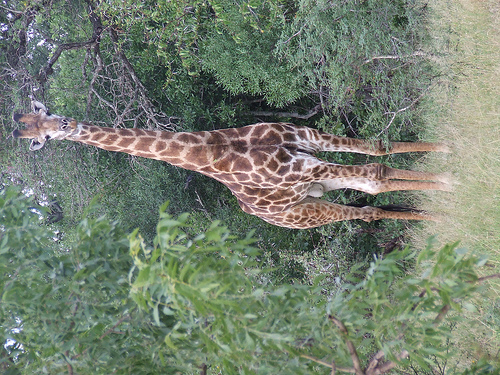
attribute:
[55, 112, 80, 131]
nose — black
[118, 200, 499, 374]
shrub — covered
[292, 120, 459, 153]
leg — long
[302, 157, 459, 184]
leg — long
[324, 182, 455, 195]
leg — long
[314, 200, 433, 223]
leg — long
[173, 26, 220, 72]
leaf — tall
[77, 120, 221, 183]
neck — extended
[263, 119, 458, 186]
legs — long, spotted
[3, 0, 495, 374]
forest — dead, tree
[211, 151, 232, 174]
spot — brown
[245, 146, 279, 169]
spot — brown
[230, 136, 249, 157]
spot — brown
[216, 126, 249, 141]
spot — brown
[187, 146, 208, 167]
spot — brown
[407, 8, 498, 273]
grass — long, green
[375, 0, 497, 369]
grass — brown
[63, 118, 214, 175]
neck — long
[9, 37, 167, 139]
branches — dead, leafless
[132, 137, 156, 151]
spot — brown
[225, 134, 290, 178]
spots — brown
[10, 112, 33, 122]
horn — black, brown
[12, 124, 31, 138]
horn — black, brown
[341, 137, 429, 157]
leg — long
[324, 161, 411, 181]
leg — long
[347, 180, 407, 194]
leg — long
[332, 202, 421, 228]
leg — long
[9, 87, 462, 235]
giraffe — standing, still, single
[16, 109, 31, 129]
horns — black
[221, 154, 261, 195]
spots — brown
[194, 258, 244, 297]
leaf — large